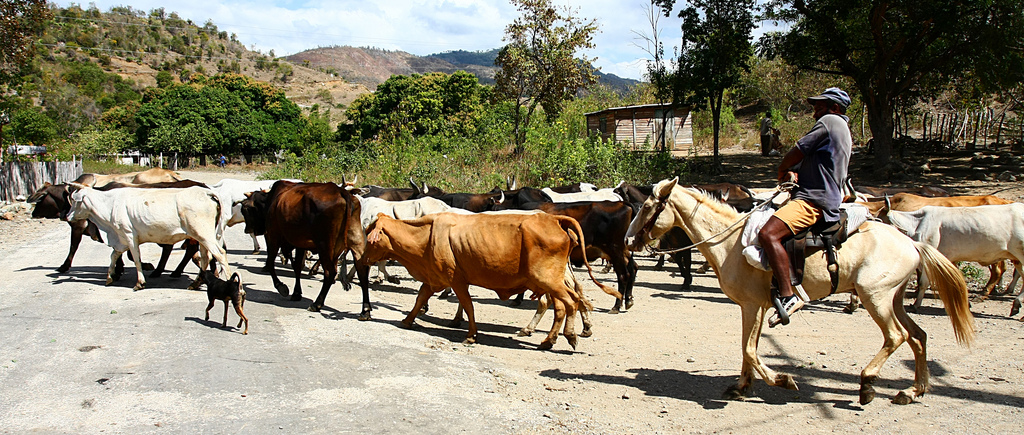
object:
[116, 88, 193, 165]
tree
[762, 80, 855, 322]
man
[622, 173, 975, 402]
horse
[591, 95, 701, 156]
shack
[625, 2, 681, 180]
trees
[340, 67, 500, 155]
tree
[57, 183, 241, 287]
cow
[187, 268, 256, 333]
dog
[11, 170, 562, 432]
path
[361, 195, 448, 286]
cow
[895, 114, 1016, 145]
fence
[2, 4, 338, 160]
mountains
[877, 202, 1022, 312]
cow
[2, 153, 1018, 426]
field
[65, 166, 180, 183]
cow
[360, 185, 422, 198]
cow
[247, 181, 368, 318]
cow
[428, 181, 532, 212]
cow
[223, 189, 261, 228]
cow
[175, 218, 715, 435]
field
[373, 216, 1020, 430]
field